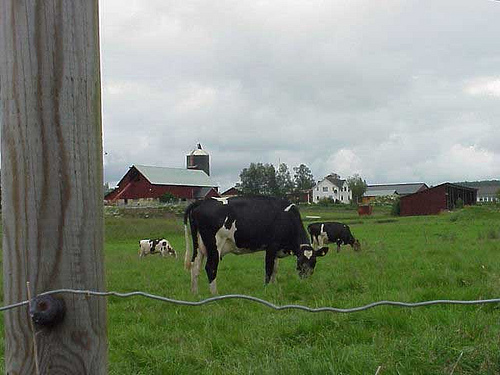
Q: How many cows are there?
A: Three.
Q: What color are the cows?
A: Black.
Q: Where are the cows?
A: The field.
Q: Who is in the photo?
A: Cows.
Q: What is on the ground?
A: Grass.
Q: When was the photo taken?
A: Day time.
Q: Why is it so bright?
A: Sunny.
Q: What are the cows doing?
A: Eating.